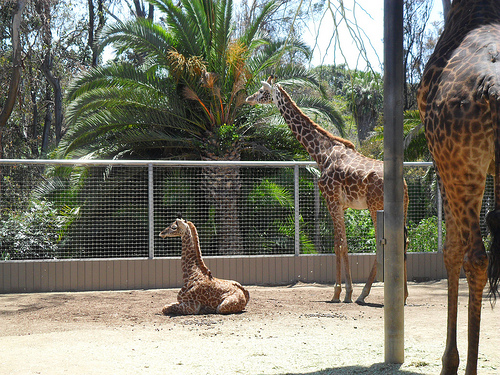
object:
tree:
[0, 0, 498, 257]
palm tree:
[37, 0, 348, 260]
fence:
[0, 158, 494, 261]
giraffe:
[416, 0, 499, 375]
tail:
[484, 139, 499, 311]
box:
[376, 210, 386, 282]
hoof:
[331, 297, 340, 303]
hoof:
[342, 299, 352, 303]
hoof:
[354, 300, 365, 305]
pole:
[384, 0, 405, 364]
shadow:
[264, 361, 433, 374]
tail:
[403, 187, 411, 262]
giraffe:
[246, 75, 409, 304]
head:
[158, 213, 189, 238]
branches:
[282, 0, 383, 134]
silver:
[143, 160, 175, 164]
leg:
[440, 171, 495, 375]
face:
[159, 222, 181, 238]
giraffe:
[159, 213, 250, 314]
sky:
[0, 0, 444, 84]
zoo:
[0, 0, 499, 375]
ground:
[0, 278, 500, 372]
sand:
[43, 298, 161, 328]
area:
[0, 158, 499, 374]